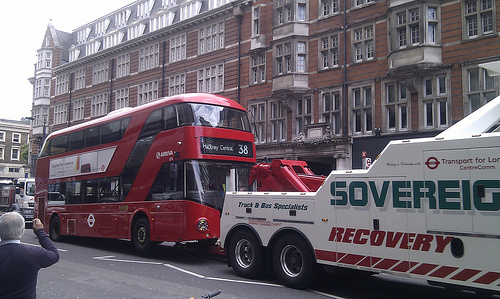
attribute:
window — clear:
[142, 159, 254, 212]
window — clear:
[175, 100, 252, 131]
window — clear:
[43, 101, 180, 202]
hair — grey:
[1, 210, 26, 239]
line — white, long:
[85, 236, 309, 297]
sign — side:
[38, 139, 141, 195]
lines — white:
[151, 258, 215, 286]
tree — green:
[18, 143, 30, 165]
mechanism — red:
[271, 159, 309, 192]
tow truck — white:
[216, 94, 498, 295]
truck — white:
[13, 172, 46, 230]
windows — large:
[28, 81, 256, 253]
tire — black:
[242, 214, 323, 296]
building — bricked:
[27, 1, 498, 179]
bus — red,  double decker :
[35, 98, 255, 250]